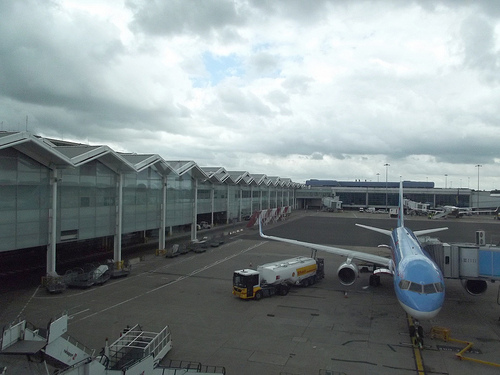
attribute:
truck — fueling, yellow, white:
[198, 231, 337, 311]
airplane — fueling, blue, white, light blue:
[236, 168, 499, 332]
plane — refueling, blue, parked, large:
[303, 192, 464, 321]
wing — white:
[238, 199, 406, 270]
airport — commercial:
[3, 123, 497, 244]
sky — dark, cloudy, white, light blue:
[2, 1, 499, 211]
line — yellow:
[389, 284, 435, 374]